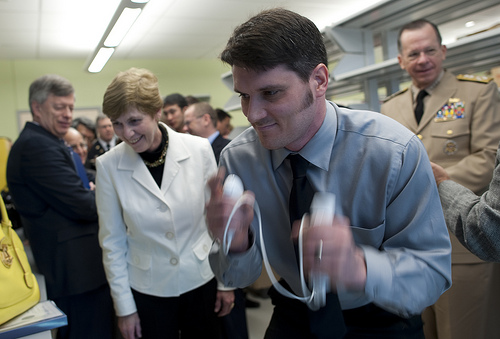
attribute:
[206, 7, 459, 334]
man — looking, crouching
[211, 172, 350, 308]
controls — white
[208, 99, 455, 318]
shirt — blue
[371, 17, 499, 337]
man — old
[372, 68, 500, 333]
uniform — brown, military, tan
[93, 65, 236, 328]
woman — smiling, watching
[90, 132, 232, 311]
jacket — white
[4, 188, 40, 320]
purse — yellow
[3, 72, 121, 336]
man — standing, leaning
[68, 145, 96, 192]
folder — blue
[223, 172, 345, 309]
controllers — game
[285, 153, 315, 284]
tie — navy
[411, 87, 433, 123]
tie — black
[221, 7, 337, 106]
hair — black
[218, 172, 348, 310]
remote — white, wii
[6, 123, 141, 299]
blazer — black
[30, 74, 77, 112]
hair — white, black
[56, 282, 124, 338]
pants — black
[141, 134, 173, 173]
necklace — silver, gold, chain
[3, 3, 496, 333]
people — looking, talking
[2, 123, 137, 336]
suit — black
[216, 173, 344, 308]
device — wired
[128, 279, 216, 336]
skirt — black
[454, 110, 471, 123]
pin — military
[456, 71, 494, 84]
pin — military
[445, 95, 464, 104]
pin — military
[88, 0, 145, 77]
lights — turned, on, overhead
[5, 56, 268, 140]
wall — green, back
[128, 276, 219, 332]
pants — black